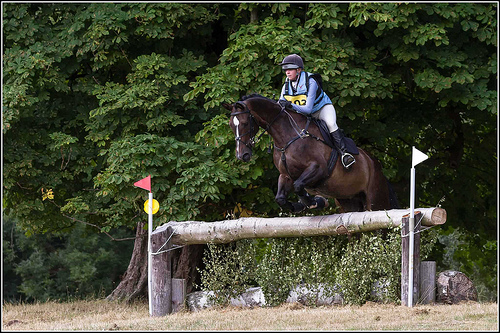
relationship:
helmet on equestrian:
[274, 51, 303, 68] [256, 49, 356, 143]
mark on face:
[231, 113, 242, 134] [217, 97, 257, 166]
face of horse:
[217, 97, 257, 166] [195, 72, 405, 257]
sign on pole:
[136, 184, 176, 227] [125, 181, 176, 319]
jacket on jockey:
[289, 80, 339, 116] [270, 34, 331, 144]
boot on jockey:
[318, 120, 354, 166] [259, 49, 377, 174]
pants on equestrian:
[311, 103, 339, 133] [256, 49, 356, 143]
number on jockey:
[276, 89, 312, 107] [272, 34, 350, 154]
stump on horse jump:
[141, 217, 191, 303] [132, 202, 452, 311]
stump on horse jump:
[167, 243, 205, 312] [130, 194, 445, 304]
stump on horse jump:
[420, 251, 444, 321] [112, 203, 472, 313]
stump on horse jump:
[139, 207, 453, 250] [138, 218, 454, 326]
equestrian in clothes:
[256, 49, 356, 143] [278, 79, 341, 122]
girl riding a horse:
[276, 53, 337, 124] [219, 87, 401, 224]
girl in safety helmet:
[276, 53, 337, 124] [265, 43, 311, 75]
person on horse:
[276, 48, 360, 169] [225, 91, 390, 220]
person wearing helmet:
[276, 48, 360, 169] [280, 50, 304, 72]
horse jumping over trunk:
[225, 91, 390, 220] [157, 203, 447, 244]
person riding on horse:
[276, 48, 360, 169] [225, 91, 390, 220]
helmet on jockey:
[274, 51, 303, 68] [273, 51, 357, 171]